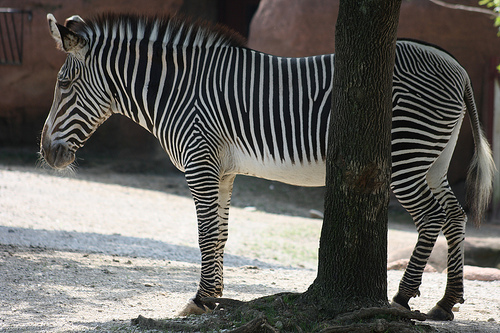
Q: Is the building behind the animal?
A: Yes, the building is behind the animal.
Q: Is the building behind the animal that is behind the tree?
A: Yes, the building is behind the animal.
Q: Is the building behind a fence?
A: No, the building is behind the animal.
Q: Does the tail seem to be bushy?
A: Yes, the tail is bushy.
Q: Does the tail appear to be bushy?
A: Yes, the tail is bushy.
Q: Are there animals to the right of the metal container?
A: Yes, there is an animal to the right of the container.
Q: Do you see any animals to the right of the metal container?
A: Yes, there is an animal to the right of the container.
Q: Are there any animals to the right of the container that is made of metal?
A: Yes, there is an animal to the right of the container.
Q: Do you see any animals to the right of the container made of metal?
A: Yes, there is an animal to the right of the container.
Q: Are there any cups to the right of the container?
A: No, there is an animal to the right of the container.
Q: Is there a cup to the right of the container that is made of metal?
A: No, there is an animal to the right of the container.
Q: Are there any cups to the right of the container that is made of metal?
A: No, there is an animal to the right of the container.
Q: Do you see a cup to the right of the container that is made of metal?
A: No, there is an animal to the right of the container.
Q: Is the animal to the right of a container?
A: Yes, the animal is to the right of a container.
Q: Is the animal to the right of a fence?
A: No, the animal is to the right of a container.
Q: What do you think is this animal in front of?
A: The animal is in front of the building.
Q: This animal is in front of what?
A: The animal is in front of the building.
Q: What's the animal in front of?
A: The animal is in front of the building.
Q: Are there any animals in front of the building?
A: Yes, there is an animal in front of the building.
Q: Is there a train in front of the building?
A: No, there is an animal in front of the building.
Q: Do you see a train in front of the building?
A: No, there is an animal in front of the building.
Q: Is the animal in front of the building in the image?
A: Yes, the animal is in front of the building.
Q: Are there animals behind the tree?
A: Yes, there is an animal behind the tree.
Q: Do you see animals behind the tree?
A: Yes, there is an animal behind the tree.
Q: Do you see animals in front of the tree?
A: No, the animal is behind the tree.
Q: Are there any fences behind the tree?
A: No, there is an animal behind the tree.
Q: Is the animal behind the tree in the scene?
A: Yes, the animal is behind the tree.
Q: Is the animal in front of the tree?
A: No, the animal is behind the tree.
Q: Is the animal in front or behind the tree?
A: The animal is behind the tree.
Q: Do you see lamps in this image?
A: No, there are no lamps.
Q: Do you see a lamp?
A: No, there are no lamps.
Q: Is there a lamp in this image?
A: No, there are no lamps.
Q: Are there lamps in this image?
A: No, there are no lamps.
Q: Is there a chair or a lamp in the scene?
A: No, there are no lamps or chairs.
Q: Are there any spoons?
A: No, there are no spoons.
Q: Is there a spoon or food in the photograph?
A: No, there are no spoons or food.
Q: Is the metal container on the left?
A: Yes, the container is on the left of the image.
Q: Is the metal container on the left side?
A: Yes, the container is on the left of the image.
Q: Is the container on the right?
A: No, the container is on the left of the image.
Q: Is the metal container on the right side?
A: No, the container is on the left of the image.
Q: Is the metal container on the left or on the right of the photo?
A: The container is on the left of the image.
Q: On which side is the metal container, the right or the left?
A: The container is on the left of the image.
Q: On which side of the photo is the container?
A: The container is on the left of the image.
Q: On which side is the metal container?
A: The container is on the left of the image.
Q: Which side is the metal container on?
A: The container is on the left of the image.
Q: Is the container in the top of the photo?
A: Yes, the container is in the top of the image.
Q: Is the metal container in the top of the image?
A: Yes, the container is in the top of the image.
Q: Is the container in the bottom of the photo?
A: No, the container is in the top of the image.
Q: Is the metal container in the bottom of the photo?
A: No, the container is in the top of the image.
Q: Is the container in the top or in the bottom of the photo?
A: The container is in the top of the image.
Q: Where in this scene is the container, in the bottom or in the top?
A: The container is in the top of the image.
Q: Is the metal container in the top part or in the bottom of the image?
A: The container is in the top of the image.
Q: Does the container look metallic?
A: Yes, the container is metallic.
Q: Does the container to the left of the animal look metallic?
A: Yes, the container is metallic.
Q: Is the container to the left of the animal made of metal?
A: Yes, the container is made of metal.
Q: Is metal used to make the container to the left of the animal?
A: Yes, the container is made of metal.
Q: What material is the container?
A: The container is made of metal.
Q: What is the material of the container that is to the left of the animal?
A: The container is made of metal.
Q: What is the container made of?
A: The container is made of metal.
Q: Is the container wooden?
A: No, the container is metallic.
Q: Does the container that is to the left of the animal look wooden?
A: No, the container is metallic.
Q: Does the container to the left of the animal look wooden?
A: No, the container is metallic.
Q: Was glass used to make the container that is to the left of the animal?
A: No, the container is made of metal.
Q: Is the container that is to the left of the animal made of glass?
A: No, the container is made of metal.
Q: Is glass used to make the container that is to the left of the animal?
A: No, the container is made of metal.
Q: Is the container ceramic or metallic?
A: The container is metallic.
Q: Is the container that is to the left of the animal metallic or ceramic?
A: The container is metallic.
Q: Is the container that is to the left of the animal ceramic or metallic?
A: The container is metallic.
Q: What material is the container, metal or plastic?
A: The container is made of metal.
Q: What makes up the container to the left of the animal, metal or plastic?
A: The container is made of metal.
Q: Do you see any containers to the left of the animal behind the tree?
A: Yes, there is a container to the left of the animal.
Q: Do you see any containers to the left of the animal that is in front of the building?
A: Yes, there is a container to the left of the animal.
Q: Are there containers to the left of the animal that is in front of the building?
A: Yes, there is a container to the left of the animal.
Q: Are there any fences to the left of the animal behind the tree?
A: No, there is a container to the left of the animal.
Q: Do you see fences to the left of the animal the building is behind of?
A: No, there is a container to the left of the animal.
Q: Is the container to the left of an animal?
A: Yes, the container is to the left of an animal.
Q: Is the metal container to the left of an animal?
A: Yes, the container is to the left of an animal.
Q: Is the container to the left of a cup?
A: No, the container is to the left of an animal.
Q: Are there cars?
A: No, there are no cars.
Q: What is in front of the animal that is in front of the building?
A: The tree is in front of the animal.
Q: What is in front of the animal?
A: The tree is in front of the animal.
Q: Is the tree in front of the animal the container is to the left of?
A: Yes, the tree is in front of the animal.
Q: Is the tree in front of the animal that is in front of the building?
A: Yes, the tree is in front of the animal.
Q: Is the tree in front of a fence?
A: No, the tree is in front of the animal.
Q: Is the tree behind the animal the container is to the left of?
A: No, the tree is in front of the animal.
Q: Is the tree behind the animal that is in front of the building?
A: No, the tree is in front of the animal.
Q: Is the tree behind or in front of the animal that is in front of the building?
A: The tree is in front of the animal.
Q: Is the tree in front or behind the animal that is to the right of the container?
A: The tree is in front of the animal.